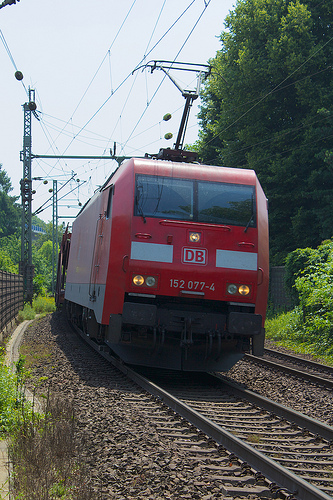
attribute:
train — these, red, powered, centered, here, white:
[70, 156, 281, 367]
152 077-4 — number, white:
[162, 277, 222, 294]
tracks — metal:
[212, 400, 296, 435]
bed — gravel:
[258, 401, 302, 413]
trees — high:
[248, 106, 325, 235]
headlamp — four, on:
[180, 227, 205, 244]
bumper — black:
[133, 308, 223, 368]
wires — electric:
[121, 21, 211, 49]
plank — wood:
[116, 377, 156, 393]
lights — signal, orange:
[218, 285, 259, 297]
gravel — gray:
[282, 347, 300, 367]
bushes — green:
[18, 286, 67, 314]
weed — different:
[14, 421, 65, 457]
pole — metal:
[35, 145, 76, 183]